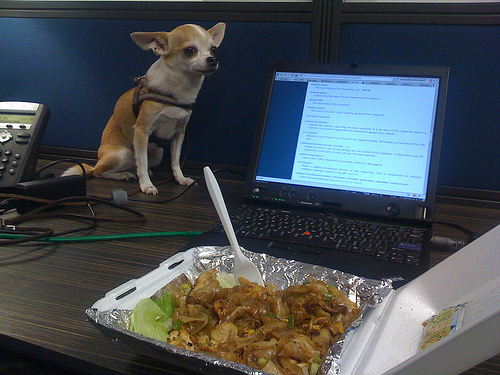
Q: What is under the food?
A: Aluminum foil.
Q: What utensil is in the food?
A: Fork.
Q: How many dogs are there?
A: 1.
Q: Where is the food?
A: In a styrofoam container.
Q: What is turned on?
A: A laptop.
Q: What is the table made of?
A: Wood.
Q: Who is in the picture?
A: No one.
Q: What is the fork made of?
A: Plastic.